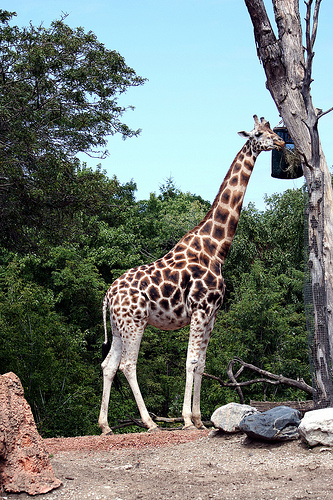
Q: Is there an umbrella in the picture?
A: No, there are no umbrellas.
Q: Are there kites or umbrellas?
A: No, there are no umbrellas or kites.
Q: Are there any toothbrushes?
A: No, there are no toothbrushes.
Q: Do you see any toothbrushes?
A: No, there are no toothbrushes.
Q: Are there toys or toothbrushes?
A: No, there are no toothbrushes or toys.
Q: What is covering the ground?
A: The dirt is covering the ground.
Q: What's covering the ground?
A: The dirt is covering the ground.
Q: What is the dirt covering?
A: The dirt is covering the ground.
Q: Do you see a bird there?
A: No, there are no birds.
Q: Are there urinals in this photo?
A: No, there are no urinals.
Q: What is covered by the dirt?
A: The ground is covered by the dirt.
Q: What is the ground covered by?
A: The ground is covered by the dirt.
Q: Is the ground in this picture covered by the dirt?
A: Yes, the ground is covered by the dirt.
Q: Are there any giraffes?
A: Yes, there is a giraffe.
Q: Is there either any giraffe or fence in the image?
A: Yes, there is a giraffe.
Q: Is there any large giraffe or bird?
A: Yes, there is a large giraffe.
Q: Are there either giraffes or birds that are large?
A: Yes, the giraffe is large.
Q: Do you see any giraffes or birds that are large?
A: Yes, the giraffe is large.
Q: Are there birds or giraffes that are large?
A: Yes, the giraffe is large.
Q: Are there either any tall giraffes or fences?
A: Yes, there is a tall giraffe.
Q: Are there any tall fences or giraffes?
A: Yes, there is a tall giraffe.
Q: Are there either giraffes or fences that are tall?
A: Yes, the giraffe is tall.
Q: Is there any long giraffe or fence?
A: Yes, there is a long giraffe.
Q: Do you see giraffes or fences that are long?
A: Yes, the giraffe is long.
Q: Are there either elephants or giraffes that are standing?
A: Yes, the giraffe is standing.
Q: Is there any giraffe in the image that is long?
A: Yes, there is a long giraffe.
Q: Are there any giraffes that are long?
A: Yes, there is a giraffe that is long.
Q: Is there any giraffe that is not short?
A: Yes, there is a long giraffe.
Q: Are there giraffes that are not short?
A: Yes, there is a long giraffe.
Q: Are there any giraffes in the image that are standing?
A: Yes, there is a giraffe that is standing.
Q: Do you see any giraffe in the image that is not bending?
A: Yes, there is a giraffe that is standing .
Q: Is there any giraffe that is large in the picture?
A: Yes, there is a large giraffe.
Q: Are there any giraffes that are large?
A: Yes, there is a giraffe that is large.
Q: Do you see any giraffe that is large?
A: Yes, there is a giraffe that is large.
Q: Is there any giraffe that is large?
A: Yes, there is a giraffe that is large.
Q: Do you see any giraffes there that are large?
A: Yes, there is a giraffe that is large.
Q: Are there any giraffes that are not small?
A: Yes, there is a large giraffe.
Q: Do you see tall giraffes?
A: Yes, there is a tall giraffe.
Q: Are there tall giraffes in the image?
A: Yes, there is a tall giraffe.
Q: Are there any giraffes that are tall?
A: Yes, there is a giraffe that is tall.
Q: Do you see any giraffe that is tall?
A: Yes, there is a giraffe that is tall.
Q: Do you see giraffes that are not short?
A: Yes, there is a tall giraffe.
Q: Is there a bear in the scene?
A: No, there are no bears.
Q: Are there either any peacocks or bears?
A: No, there are no bears or peacocks.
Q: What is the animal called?
A: The animal is a giraffe.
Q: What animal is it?
A: The animal is a giraffe.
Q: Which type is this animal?
A: That is a giraffe.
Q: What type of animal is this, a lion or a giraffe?
A: That is a giraffe.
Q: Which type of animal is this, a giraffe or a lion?
A: That is a giraffe.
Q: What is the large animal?
A: The animal is a giraffe.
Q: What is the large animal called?
A: The animal is a giraffe.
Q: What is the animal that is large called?
A: The animal is a giraffe.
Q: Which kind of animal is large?
A: The animal is a giraffe.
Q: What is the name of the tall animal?
A: The animal is a giraffe.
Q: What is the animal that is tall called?
A: The animal is a giraffe.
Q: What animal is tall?
A: The animal is a giraffe.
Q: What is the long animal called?
A: The animal is a giraffe.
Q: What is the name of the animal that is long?
A: The animal is a giraffe.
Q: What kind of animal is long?
A: The animal is a giraffe.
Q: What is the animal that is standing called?
A: The animal is a giraffe.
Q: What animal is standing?
A: The animal is a giraffe.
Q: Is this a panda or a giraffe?
A: This is a giraffe.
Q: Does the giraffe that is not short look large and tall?
A: Yes, the giraffe is large and tall.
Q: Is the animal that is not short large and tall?
A: Yes, the giraffe is large and tall.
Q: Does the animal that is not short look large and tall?
A: Yes, the giraffe is large and tall.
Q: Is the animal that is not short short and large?
A: No, the giraffe is large but tall.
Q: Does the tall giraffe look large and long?
A: Yes, the giraffe is large and long.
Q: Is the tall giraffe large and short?
A: No, the giraffe is large but long.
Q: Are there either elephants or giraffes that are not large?
A: No, there is a giraffe but it is large.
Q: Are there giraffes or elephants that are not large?
A: No, there is a giraffe but it is large.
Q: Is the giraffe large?
A: Yes, the giraffe is large.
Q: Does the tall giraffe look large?
A: Yes, the giraffe is large.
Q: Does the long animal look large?
A: Yes, the giraffe is large.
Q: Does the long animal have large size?
A: Yes, the giraffe is large.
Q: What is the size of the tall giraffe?
A: The giraffe is large.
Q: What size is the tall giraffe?
A: The giraffe is large.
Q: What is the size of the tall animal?
A: The giraffe is large.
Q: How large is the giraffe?
A: The giraffe is large.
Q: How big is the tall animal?
A: The giraffe is large.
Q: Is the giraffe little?
A: No, the giraffe is large.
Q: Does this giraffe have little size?
A: No, the giraffe is large.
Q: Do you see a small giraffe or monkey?
A: No, there is a giraffe but it is large.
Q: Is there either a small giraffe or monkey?
A: No, there is a giraffe but it is large.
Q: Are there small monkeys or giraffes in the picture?
A: No, there is a giraffe but it is large.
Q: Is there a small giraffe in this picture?
A: No, there is a giraffe but it is large.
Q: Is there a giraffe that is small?
A: No, there is a giraffe but it is large.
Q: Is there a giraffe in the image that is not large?
A: No, there is a giraffe but it is large.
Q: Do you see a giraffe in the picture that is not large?
A: No, there is a giraffe but it is large.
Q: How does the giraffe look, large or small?
A: The giraffe is large.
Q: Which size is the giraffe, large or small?
A: The giraffe is large.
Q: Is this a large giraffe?
A: Yes, this is a large giraffe.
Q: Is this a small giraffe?
A: No, this is a large giraffe.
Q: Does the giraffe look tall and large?
A: Yes, the giraffe is tall and large.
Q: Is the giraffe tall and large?
A: Yes, the giraffe is tall and large.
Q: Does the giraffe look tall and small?
A: No, the giraffe is tall but large.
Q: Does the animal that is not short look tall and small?
A: No, the giraffe is tall but large.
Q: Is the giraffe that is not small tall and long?
A: Yes, the giraffe is tall and long.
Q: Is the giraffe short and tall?
A: No, the giraffe is tall but long.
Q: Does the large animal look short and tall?
A: No, the giraffe is tall but long.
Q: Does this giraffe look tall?
A: Yes, the giraffe is tall.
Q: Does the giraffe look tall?
A: Yes, the giraffe is tall.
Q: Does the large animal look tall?
A: Yes, the giraffe is tall.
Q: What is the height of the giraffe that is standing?
A: The giraffe is tall.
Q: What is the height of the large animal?
A: The giraffe is tall.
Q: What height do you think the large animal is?
A: The giraffe is tall.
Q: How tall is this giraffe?
A: The giraffe is tall.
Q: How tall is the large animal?
A: The giraffe is tall.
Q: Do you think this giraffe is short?
A: No, the giraffe is tall.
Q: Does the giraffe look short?
A: No, the giraffe is tall.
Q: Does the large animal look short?
A: No, the giraffe is tall.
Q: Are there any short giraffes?
A: No, there is a giraffe but it is tall.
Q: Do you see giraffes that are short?
A: No, there is a giraffe but it is tall.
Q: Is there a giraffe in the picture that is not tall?
A: No, there is a giraffe but it is tall.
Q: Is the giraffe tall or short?
A: The giraffe is tall.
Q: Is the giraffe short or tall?
A: The giraffe is tall.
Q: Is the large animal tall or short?
A: The giraffe is tall.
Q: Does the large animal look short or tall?
A: The giraffe is tall.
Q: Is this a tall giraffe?
A: Yes, this is a tall giraffe.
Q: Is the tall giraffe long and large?
A: Yes, the giraffe is long and large.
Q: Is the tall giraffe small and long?
A: No, the giraffe is long but large.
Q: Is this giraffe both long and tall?
A: Yes, the giraffe is long and tall.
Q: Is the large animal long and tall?
A: Yes, the giraffe is long and tall.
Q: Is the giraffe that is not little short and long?
A: No, the giraffe is long but tall.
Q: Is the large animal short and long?
A: No, the giraffe is long but tall.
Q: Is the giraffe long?
A: Yes, the giraffe is long.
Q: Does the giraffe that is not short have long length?
A: Yes, the giraffe is long.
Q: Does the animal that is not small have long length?
A: Yes, the giraffe is long.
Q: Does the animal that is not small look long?
A: Yes, the giraffe is long.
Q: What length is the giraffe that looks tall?
A: The giraffe is long.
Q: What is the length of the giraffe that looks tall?
A: The giraffe is long.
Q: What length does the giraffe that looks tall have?
A: The giraffe has long length.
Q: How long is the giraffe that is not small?
A: The giraffe is long.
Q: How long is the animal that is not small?
A: The giraffe is long.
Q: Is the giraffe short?
A: No, the giraffe is long.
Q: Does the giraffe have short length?
A: No, the giraffe is long.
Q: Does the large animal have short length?
A: No, the giraffe is long.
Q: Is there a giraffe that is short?
A: No, there is a giraffe but it is long.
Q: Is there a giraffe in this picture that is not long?
A: No, there is a giraffe but it is long.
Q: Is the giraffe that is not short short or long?
A: The giraffe is long.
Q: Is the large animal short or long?
A: The giraffe is long.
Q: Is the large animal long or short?
A: The giraffe is long.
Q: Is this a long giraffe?
A: Yes, this is a long giraffe.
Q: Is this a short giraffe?
A: No, this is a long giraffe.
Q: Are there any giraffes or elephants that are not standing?
A: No, there is a giraffe but it is standing.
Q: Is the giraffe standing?
A: Yes, the giraffe is standing.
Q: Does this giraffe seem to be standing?
A: Yes, the giraffe is standing.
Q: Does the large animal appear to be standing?
A: Yes, the giraffe is standing.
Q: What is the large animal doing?
A: The giraffe is standing.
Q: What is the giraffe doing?
A: The giraffe is standing.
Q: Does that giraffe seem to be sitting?
A: No, the giraffe is standing.